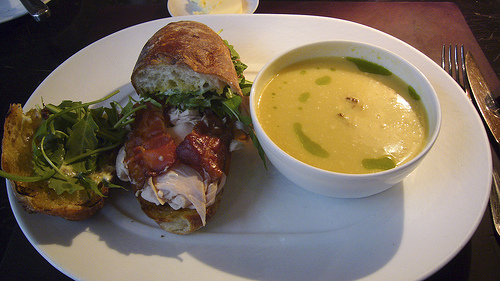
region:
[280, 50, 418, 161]
The yellow soup/cheese in the bowl.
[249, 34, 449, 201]
The white bowl on the plate.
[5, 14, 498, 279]
The big plate in the center.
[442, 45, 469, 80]
The points on the fork.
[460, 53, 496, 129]
The blade of the butter knife.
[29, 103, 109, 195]
The greens on the sandwich bread on the left.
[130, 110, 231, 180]
The bacon on the sandwich on the right.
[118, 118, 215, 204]
The sliced turkey on the sandwich on the right.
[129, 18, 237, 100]
The top piece of the bread of the sandwich on the right.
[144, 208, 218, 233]
The bottom piece of the bread of the sandwich on the right.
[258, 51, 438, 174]
split pea soup in a white bowl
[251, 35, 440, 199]
white bowl full of soup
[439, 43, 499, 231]
fork under the white plate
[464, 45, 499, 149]
metal knife next to the plate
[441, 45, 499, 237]
fork and knife next to the plate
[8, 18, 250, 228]
sandwhich on the white plate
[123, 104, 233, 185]
strips of bacon on the sandwhich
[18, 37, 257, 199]
lettuce on the sandwhich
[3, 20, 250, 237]
toasted sandwhich on the plate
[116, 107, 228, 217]
ham on the toasted sandwhich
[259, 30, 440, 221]
Bowl of yellow soup with oil floating on the top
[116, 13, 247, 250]
Sandwich with lettuce, turkey. and pork on a baguette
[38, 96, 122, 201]
Lettuce on a piece of sandwich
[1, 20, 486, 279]
Round, white plate containing soup and a sandwich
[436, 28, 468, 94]
Fork to the right of the plate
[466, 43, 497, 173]
Knife to the right of the plate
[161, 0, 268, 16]
Small bowl of butter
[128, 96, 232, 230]
Meat on the sandwich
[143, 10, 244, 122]
Part of a baguette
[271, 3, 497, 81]
Brown place mat in background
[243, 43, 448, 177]
a bowl of soup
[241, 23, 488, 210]
a white bowl with soup in it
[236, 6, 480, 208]
a bowl sitting on a plate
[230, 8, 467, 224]
a bowl sitting on a table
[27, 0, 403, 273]
food on a white plate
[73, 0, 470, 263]
a plate full of food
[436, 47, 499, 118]
a fork on a table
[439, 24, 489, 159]
a fork near a plate of food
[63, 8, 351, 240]
food on a plate with a bowl of soup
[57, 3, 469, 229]
a white plate with some food on it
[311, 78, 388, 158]
A bowl of soup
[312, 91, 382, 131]
Soup in a bowl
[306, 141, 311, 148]
A greenish mark in the soup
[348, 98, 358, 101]
A brownish object in soup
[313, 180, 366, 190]
The outside of a bowl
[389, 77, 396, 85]
Shadow cast by bowl in the soup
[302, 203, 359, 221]
Shadow cast on the plate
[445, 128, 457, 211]
A plate on the table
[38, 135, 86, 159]
Greens on a slice of bread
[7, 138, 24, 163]
A slice of bread